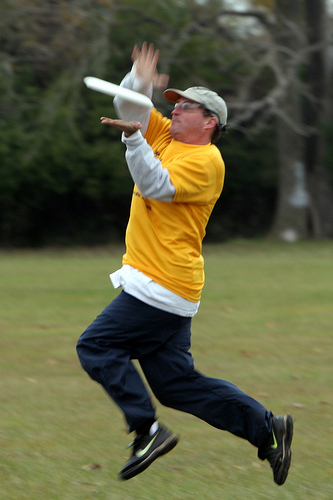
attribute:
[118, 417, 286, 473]
shoes — black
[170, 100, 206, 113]
eyeglasses — metal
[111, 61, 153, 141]
sleeve — gray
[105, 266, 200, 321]
teeshirt — white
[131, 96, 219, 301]
shirt — yellow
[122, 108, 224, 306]
shirt — yellow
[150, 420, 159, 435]
socks — white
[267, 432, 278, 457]
check mark — green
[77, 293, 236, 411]
pants — navy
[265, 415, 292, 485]
sneaker — black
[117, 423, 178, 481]
sneaker — black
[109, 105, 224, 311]
t shirt — yellow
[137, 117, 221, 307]
t-shirt — bright yellow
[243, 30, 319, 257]
trunk — LARGE, TREE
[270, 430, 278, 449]
stripe — white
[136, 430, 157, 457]
stripe — white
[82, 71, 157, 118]
frisbee — white